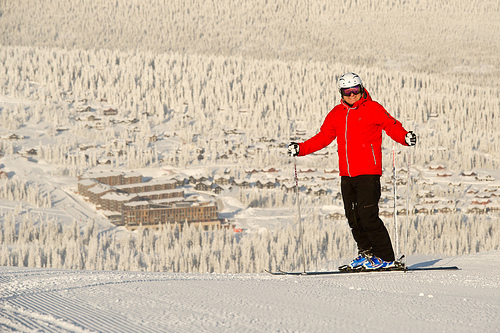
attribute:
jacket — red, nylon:
[322, 120, 385, 175]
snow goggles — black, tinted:
[337, 84, 365, 96]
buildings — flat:
[78, 170, 235, 233]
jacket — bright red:
[321, 101, 389, 161]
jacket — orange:
[294, 92, 406, 188]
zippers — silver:
[342, 101, 352, 176]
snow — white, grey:
[3, 1, 497, 329]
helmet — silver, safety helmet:
[337, 71, 363, 96]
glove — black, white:
[400, 129, 422, 149]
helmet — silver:
[337, 74, 369, 89]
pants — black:
[337, 173, 402, 261]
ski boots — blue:
[341, 247, 403, 267]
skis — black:
[266, 265, 468, 277]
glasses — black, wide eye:
[342, 84, 367, 98]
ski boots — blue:
[345, 250, 402, 276]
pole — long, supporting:
[287, 130, 311, 273]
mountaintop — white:
[11, 253, 482, 328]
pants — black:
[326, 168, 401, 263]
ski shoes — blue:
[343, 247, 400, 268]